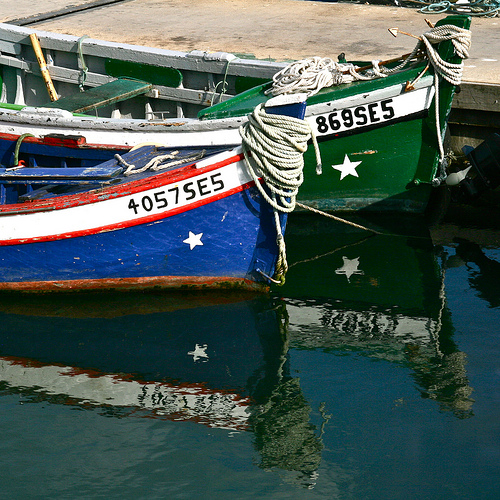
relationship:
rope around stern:
[238, 60, 314, 222] [233, 98, 314, 300]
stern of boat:
[233, 98, 314, 300] [10, 101, 305, 283]